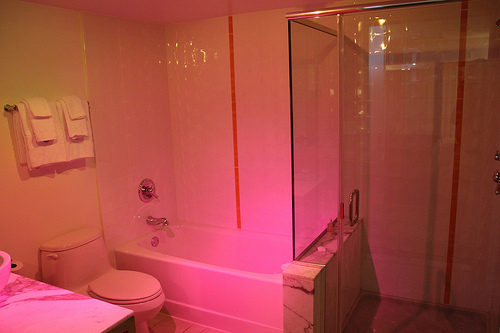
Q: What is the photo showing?
A: It is showing a bathroom.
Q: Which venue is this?
A: This is a bathroom.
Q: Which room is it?
A: It is a bathroom.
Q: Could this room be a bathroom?
A: Yes, it is a bathroom.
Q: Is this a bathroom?
A: Yes, it is a bathroom.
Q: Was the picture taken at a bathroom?
A: Yes, it was taken in a bathroom.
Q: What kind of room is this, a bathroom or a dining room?
A: It is a bathroom.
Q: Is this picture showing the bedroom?
A: No, the picture is showing the bathroom.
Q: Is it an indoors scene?
A: Yes, it is indoors.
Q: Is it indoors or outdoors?
A: It is indoors.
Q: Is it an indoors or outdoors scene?
A: It is indoors.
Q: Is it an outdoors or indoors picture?
A: It is indoors.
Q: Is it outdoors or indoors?
A: It is indoors.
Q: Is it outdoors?
A: No, it is indoors.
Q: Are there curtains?
A: No, there are no curtains.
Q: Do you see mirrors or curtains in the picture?
A: No, there are no curtains or mirrors.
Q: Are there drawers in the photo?
A: No, there are no drawers.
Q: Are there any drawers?
A: No, there are no drawers.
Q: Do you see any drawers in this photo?
A: No, there are no drawers.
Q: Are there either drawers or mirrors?
A: No, there are no drawers or mirrors.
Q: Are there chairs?
A: No, there are no chairs.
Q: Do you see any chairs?
A: No, there are no chairs.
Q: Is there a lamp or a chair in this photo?
A: No, there are no chairs or lamps.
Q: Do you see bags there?
A: No, there are no bags.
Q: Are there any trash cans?
A: No, there are no trash cans.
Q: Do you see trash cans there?
A: No, there are no trash cans.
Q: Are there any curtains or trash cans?
A: No, there are no trash cans or curtains.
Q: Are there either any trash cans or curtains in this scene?
A: No, there are no trash cans or curtains.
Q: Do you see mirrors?
A: No, there are no mirrors.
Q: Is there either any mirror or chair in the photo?
A: No, there are no mirrors or chairs.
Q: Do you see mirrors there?
A: No, there are no mirrors.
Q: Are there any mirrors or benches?
A: No, there are no mirrors or benches.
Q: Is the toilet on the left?
A: Yes, the toilet is on the left of the image.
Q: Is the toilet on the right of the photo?
A: No, the toilet is on the left of the image.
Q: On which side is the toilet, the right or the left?
A: The toilet is on the left of the image.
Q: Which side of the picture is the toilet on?
A: The toilet is on the left of the image.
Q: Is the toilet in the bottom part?
A: Yes, the toilet is in the bottom of the image.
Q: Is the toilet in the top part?
A: No, the toilet is in the bottom of the image.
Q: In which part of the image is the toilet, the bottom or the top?
A: The toilet is in the bottom of the image.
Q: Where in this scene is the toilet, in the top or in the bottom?
A: The toilet is in the bottom of the image.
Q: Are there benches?
A: No, there are no benches.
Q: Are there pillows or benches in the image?
A: No, there are no benches or pillows.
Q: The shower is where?
A: The shower is in the bathroom.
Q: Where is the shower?
A: The shower is in the bathroom.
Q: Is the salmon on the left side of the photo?
A: Yes, the salmon is on the left of the image.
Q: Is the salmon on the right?
A: No, the salmon is on the left of the image.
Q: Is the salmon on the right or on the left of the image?
A: The salmon is on the left of the image.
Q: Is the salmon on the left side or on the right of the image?
A: The salmon is on the left of the image.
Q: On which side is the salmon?
A: The salmon is on the left of the image.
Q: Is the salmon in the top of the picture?
A: Yes, the salmon is in the top of the image.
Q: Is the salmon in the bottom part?
A: No, the salmon is in the top of the image.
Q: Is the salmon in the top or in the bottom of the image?
A: The salmon is in the top of the image.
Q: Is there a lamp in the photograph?
A: No, there are no lamps.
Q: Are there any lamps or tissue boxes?
A: No, there are no lamps or tissue boxes.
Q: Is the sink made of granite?
A: Yes, the sink is made of granite.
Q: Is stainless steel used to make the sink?
A: No, the sink is made of granite.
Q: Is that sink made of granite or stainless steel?
A: The sink is made of granite.